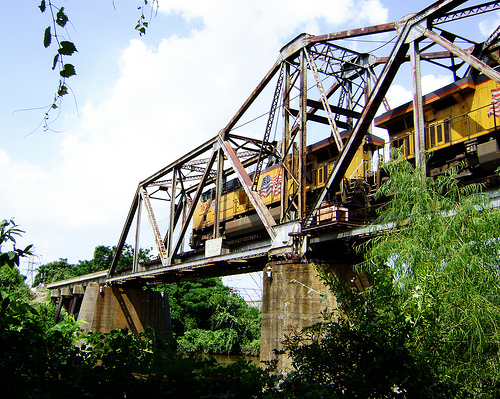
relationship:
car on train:
[183, 122, 383, 256] [188, 63, 499, 250]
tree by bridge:
[351, 143, 498, 386] [29, 3, 498, 378]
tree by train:
[351, 143, 498, 386] [188, 63, 499, 250]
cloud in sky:
[0, 0, 499, 262] [0, 0, 499, 261]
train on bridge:
[183, 39, 499, 248] [29, 3, 498, 378]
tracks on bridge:
[33, 187, 498, 301] [29, 3, 498, 378]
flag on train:
[258, 173, 285, 195] [188, 63, 499, 250]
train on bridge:
[188, 63, 499, 250] [29, 3, 498, 378]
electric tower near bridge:
[21, 242, 41, 294] [40, 270, 100, 290]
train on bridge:
[188, 63, 499, 250] [40, 270, 100, 290]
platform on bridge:
[297, 195, 364, 236] [0, 28, 497, 355]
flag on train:
[258, 174, 282, 199] [166, 115, 475, 252]